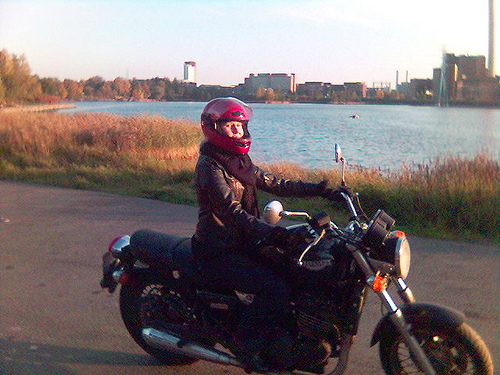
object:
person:
[187, 97, 298, 368]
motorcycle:
[100, 148, 499, 374]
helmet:
[201, 97, 251, 153]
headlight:
[391, 230, 413, 280]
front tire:
[379, 307, 494, 374]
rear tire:
[118, 269, 216, 366]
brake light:
[108, 233, 130, 253]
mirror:
[262, 200, 286, 226]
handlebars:
[263, 223, 314, 239]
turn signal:
[296, 224, 326, 267]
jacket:
[193, 151, 316, 248]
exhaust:
[140, 327, 235, 361]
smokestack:
[487, 4, 494, 73]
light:
[372, 276, 387, 292]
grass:
[45, 166, 188, 190]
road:
[0, 238, 500, 373]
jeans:
[213, 257, 298, 349]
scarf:
[207, 148, 257, 214]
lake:
[253, 101, 499, 164]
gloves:
[239, 210, 285, 244]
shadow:
[6, 340, 167, 368]